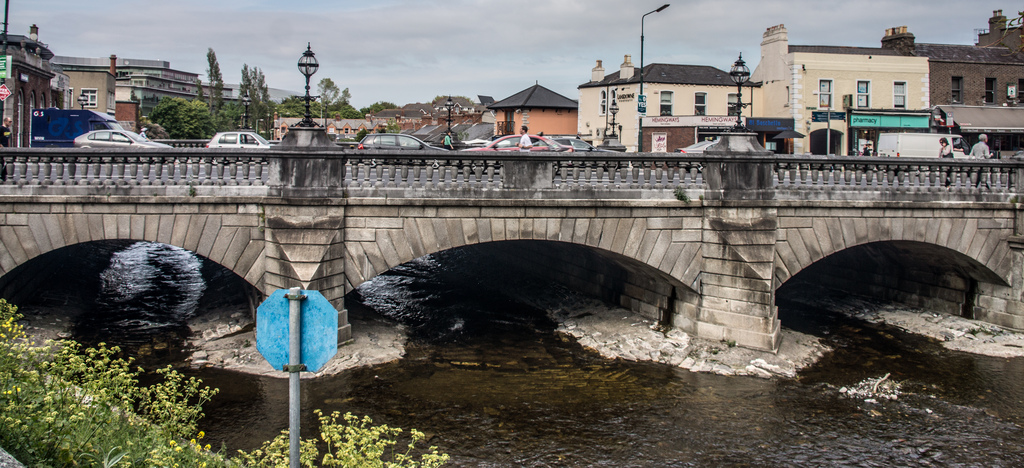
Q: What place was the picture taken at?
A: It was taken at the city.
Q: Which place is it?
A: It is a city.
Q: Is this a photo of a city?
A: Yes, it is showing a city.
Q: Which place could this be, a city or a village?
A: It is a city.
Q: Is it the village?
A: No, it is the city.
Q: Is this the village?
A: No, it is the city.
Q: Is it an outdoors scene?
A: Yes, it is outdoors.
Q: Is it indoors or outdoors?
A: It is outdoors.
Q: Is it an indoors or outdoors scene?
A: It is outdoors.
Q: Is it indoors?
A: No, it is outdoors.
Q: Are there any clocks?
A: No, there are no clocks.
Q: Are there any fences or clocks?
A: No, there are no clocks or fences.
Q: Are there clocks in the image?
A: No, there are no clocks.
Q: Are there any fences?
A: No, there are no fences.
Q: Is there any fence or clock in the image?
A: No, there are no fences or clocks.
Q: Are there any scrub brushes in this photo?
A: No, there are no scrub brushes.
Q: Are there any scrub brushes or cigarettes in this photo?
A: No, there are no scrub brushes or cigarettes.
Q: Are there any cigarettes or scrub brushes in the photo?
A: No, there are no scrub brushes or cigarettes.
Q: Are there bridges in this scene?
A: Yes, there is a bridge.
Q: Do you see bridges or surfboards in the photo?
A: Yes, there is a bridge.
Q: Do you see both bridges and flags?
A: No, there is a bridge but no flags.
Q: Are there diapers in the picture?
A: No, there are no diapers.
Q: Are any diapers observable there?
A: No, there are no diapers.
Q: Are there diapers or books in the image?
A: No, there are no diapers or books.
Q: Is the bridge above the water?
A: Yes, the bridge is above the water.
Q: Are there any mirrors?
A: No, there are no mirrors.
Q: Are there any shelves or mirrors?
A: No, there are no mirrors or shelves.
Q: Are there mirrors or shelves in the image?
A: No, there are no mirrors or shelves.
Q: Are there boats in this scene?
A: No, there are no boats.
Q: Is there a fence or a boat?
A: No, there are no boats or fences.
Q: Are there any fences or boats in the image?
A: No, there are no boats or fences.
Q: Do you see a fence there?
A: No, there are no fences.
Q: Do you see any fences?
A: No, there are no fences.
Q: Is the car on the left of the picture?
A: Yes, the car is on the left of the image.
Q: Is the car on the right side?
A: No, the car is on the left of the image.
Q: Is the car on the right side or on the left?
A: The car is on the left of the image.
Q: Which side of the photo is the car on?
A: The car is on the left of the image.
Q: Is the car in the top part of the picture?
A: Yes, the car is in the top of the image.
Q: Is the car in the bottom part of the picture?
A: No, the car is in the top of the image.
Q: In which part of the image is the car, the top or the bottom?
A: The car is in the top of the image.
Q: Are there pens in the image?
A: No, there are no pens.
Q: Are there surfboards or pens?
A: No, there are no pens or surfboards.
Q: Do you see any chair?
A: No, there are no chairs.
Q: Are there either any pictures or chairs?
A: No, there are no chairs or pictures.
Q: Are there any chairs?
A: No, there are no chairs.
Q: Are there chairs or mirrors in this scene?
A: No, there are no chairs or mirrors.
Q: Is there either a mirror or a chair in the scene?
A: No, there are no chairs or mirrors.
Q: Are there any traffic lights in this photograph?
A: No, there are no traffic lights.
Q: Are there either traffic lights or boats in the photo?
A: No, there are no traffic lights or boats.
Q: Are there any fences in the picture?
A: No, there are no fences.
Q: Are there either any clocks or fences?
A: No, there are no fences or clocks.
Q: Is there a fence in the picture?
A: No, there are no fences.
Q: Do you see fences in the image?
A: No, there are no fences.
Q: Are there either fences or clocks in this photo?
A: No, there are no fences or clocks.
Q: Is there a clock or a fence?
A: No, there are no fences or clocks.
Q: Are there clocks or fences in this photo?
A: No, there are no fences or clocks.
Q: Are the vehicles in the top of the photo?
A: Yes, the vehicles are in the top of the image.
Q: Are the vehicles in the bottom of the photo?
A: No, the vehicles are in the top of the image.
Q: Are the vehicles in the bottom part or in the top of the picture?
A: The vehicles are in the top of the image.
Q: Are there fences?
A: No, there are no fences.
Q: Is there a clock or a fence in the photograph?
A: No, there are no fences or clocks.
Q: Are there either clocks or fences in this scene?
A: No, there are no fences or clocks.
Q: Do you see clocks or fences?
A: No, there are no fences or clocks.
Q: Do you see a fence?
A: No, there are no fences.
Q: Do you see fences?
A: No, there are no fences.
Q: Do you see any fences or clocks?
A: No, there are no fences or clocks.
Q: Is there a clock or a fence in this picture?
A: No, there are no fences or clocks.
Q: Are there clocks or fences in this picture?
A: No, there are no fences or clocks.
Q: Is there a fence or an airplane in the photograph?
A: No, there are no fences or airplanes.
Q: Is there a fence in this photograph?
A: No, there are no fences.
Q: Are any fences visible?
A: No, there are no fences.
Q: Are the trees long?
A: Yes, the trees are long.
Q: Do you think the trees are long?
A: Yes, the trees are long.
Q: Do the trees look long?
A: Yes, the trees are long.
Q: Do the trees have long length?
A: Yes, the trees are long.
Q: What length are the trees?
A: The trees are long.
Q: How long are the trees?
A: The trees are long.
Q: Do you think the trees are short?
A: No, the trees are long.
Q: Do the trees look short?
A: No, the trees are long.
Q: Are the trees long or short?
A: The trees are long.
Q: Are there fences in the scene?
A: No, there are no fences.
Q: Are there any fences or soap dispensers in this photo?
A: No, there are no fences or soap dispensers.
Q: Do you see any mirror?
A: No, there are no mirrors.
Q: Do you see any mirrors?
A: No, there are no mirrors.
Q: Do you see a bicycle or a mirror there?
A: No, there are no mirrors or bicycles.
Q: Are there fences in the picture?
A: No, there are no fences.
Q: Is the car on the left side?
A: Yes, the car is on the left of the image.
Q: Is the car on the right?
A: No, the car is on the left of the image.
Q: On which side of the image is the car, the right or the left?
A: The car is on the left of the image.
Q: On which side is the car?
A: The car is on the left of the image.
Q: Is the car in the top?
A: Yes, the car is in the top of the image.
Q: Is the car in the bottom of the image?
A: No, the car is in the top of the image.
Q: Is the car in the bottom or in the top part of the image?
A: The car is in the top of the image.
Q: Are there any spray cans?
A: No, there are no spray cans.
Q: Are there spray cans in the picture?
A: No, there are no spray cans.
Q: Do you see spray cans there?
A: No, there are no spray cans.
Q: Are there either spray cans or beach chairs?
A: No, there are no spray cans or beach chairs.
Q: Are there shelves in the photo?
A: No, there are no shelves.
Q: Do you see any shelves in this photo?
A: No, there are no shelves.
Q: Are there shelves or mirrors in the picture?
A: No, there are no shelves or mirrors.